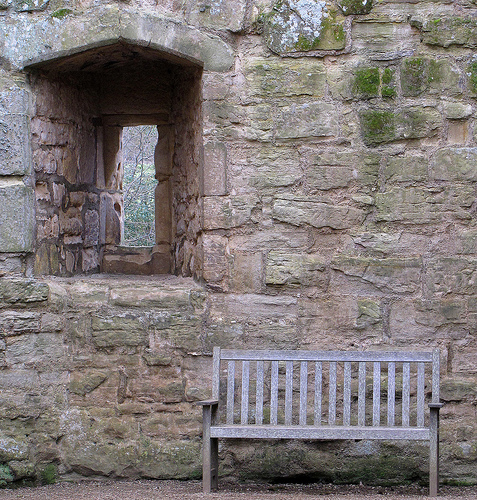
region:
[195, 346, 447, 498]
sitting bench near the wall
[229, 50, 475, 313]
building made with stone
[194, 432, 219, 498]
stand of the sitting bench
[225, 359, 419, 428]
stripped design sitting bench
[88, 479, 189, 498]
dirt with small stones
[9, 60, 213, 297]
square shaped window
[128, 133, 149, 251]
trees with branches and leaves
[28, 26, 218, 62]
wall made with stones and concrete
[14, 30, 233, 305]
window in the wall.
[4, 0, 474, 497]
Brick wall behind the bench.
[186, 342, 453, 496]
Bench by the wall.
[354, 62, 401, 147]
Moss on the wall.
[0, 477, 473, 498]
Dirt on the ground.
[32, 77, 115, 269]
Brick wall inside the hole.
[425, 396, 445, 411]
Arm on the bench.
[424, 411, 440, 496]
Leg on the bench.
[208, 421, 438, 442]
Seat on the bench.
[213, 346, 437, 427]
Back on the bench.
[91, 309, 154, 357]
Part of stone wall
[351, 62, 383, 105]
Moss growing on stone wall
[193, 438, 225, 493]
Part of wooden bench leg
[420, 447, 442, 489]
Part of wooden bench leg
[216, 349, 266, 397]
Part of wooden bench slats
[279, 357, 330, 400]
Part of wooden bench slats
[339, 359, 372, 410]
Part of wooden bench slats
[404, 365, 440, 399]
Part of wooden bench slats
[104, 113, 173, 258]
Stone doorway leading to woods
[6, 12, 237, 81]
Stone archway leading to woods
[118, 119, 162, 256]
an opening in wall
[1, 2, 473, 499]
a concrete wall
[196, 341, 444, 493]
a wooden bench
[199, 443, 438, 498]
the legs of bench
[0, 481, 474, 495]
dirt on ground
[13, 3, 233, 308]
a pentgon shape opening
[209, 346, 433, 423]
back of bench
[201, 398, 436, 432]
the arms of bench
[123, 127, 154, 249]
trees on other side of wall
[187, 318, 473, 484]
bench by a rock wall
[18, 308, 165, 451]
stone wall of a building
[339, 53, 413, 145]
moss on a stone wall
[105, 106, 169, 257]
window in a building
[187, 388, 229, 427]
arm rest of a bench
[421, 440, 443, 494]
leg of a bench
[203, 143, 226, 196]
brick on a building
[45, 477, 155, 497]
ground under a bench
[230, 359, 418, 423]
back of a bench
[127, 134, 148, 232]
trees behind the window